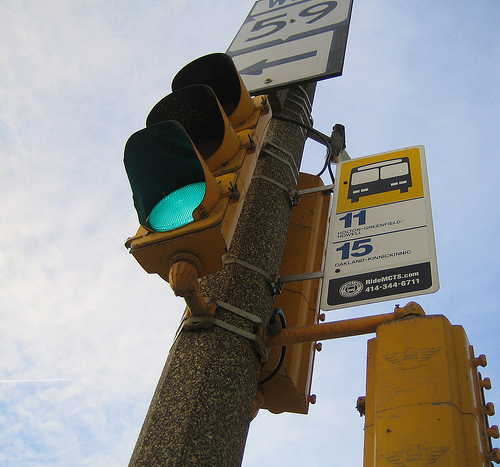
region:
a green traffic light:
[62, 52, 363, 304]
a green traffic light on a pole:
[92, 70, 311, 295]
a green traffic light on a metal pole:
[100, 55, 358, 400]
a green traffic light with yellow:
[76, 81, 391, 362]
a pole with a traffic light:
[150, 46, 315, 419]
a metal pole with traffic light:
[117, 73, 281, 355]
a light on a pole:
[125, 61, 372, 423]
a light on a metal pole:
[118, 34, 306, 396]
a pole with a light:
[135, 27, 275, 424]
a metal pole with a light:
[90, 53, 385, 386]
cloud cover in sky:
[2, 4, 495, 464]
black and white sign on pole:
[223, 0, 353, 88]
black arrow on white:
[241, 45, 319, 80]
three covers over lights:
[126, 51, 248, 241]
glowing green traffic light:
[147, 182, 207, 231]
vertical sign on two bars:
[291, 144, 437, 326]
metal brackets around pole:
[182, 92, 313, 357]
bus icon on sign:
[338, 149, 421, 210]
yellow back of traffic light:
[363, 315, 491, 465]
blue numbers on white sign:
[336, 207, 376, 263]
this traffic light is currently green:
[117, 47, 277, 292]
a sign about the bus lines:
[316, 138, 445, 316]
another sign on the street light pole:
[223, 0, 357, 89]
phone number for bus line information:
[333, 265, 429, 300]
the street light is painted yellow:
[113, 48, 278, 309]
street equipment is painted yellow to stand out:
[284, 303, 497, 465]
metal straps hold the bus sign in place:
[208, 168, 340, 295]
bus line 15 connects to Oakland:
[331, 234, 381, 273]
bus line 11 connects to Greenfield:
[335, 205, 412, 232]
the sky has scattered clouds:
[6, 4, 499, 183]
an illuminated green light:
[122, 52, 274, 282]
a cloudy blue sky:
[1, 1, 499, 463]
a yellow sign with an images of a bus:
[333, 145, 423, 214]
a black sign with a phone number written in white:
[327, 259, 433, 308]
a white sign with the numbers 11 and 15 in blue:
[318, 141, 441, 306]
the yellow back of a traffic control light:
[356, 299, 499, 464]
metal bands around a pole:
[171, 298, 268, 350]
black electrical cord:
[259, 302, 288, 389]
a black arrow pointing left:
[236, 47, 317, 77]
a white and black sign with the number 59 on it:
[224, 0, 353, 93]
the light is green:
[104, 125, 227, 262]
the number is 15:
[339, 228, 374, 270]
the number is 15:
[334, 238, 390, 282]